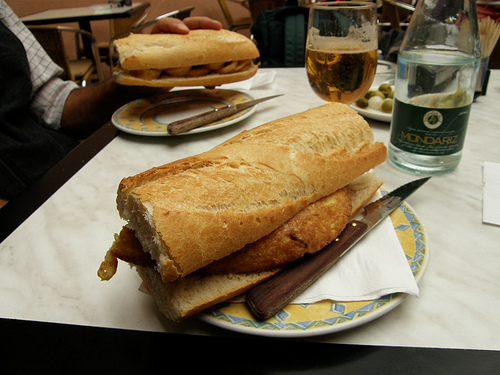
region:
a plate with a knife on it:
[115, 92, 280, 138]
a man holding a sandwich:
[1, 4, 268, 98]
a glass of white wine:
[298, 6, 386, 108]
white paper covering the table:
[3, 184, 120, 349]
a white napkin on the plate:
[306, 231, 424, 336]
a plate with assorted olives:
[364, 76, 392, 123]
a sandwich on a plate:
[104, 93, 391, 327]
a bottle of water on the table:
[383, 5, 483, 189]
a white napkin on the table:
[472, 152, 498, 229]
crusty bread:
[106, 126, 399, 251]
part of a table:
[438, 290, 473, 349]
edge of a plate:
[277, 302, 330, 354]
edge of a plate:
[383, 337, 420, 364]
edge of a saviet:
[394, 280, 418, 295]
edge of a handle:
[268, 284, 289, 301]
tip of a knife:
[414, 159, 439, 184]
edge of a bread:
[174, 253, 209, 280]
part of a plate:
[319, 306, 350, 327]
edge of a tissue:
[371, 293, 421, 304]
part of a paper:
[432, 285, 467, 328]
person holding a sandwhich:
[105, 3, 242, 115]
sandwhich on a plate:
[121, 128, 372, 250]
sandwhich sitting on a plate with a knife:
[150, 139, 392, 309]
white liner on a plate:
[317, 225, 421, 309]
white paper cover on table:
[35, 178, 137, 325]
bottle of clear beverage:
[391, 5, 476, 160]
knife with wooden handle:
[172, 92, 282, 139]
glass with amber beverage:
[297, 1, 385, 112]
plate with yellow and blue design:
[385, 208, 436, 283]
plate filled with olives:
[354, 66, 406, 116]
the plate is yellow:
[241, 295, 373, 334]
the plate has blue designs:
[222, 297, 364, 339]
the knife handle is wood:
[265, 220, 365, 310]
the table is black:
[5, 333, 187, 370]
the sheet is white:
[34, 209, 131, 319]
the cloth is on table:
[9, 211, 157, 373]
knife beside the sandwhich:
[157, 125, 419, 297]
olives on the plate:
[362, 73, 408, 117]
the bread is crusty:
[120, 137, 304, 234]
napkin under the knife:
[267, 192, 416, 305]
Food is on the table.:
[0, 30, 493, 359]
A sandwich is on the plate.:
[85, 92, 425, 345]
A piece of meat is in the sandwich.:
[83, 170, 360, 290]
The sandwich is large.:
[82, 95, 397, 342]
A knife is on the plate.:
[225, 157, 439, 332]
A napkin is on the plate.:
[248, 208, 432, 325]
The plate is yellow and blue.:
[190, 197, 430, 359]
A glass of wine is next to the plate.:
[291, 2, 382, 117]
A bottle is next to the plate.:
[362, 2, 492, 186]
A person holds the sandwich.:
[82, 8, 268, 104]